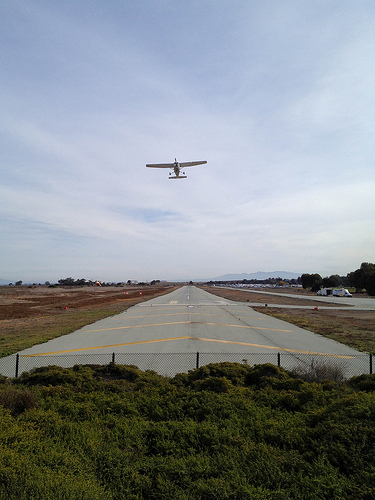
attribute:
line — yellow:
[14, 334, 362, 362]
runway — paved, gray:
[1, 286, 374, 379]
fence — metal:
[2, 352, 374, 374]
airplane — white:
[145, 159, 207, 181]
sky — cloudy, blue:
[1, 0, 374, 284]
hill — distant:
[206, 268, 300, 280]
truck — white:
[334, 287, 355, 299]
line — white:
[140, 301, 241, 308]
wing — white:
[178, 159, 208, 168]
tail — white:
[170, 175, 187, 179]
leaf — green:
[2, 375, 7, 379]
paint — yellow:
[65, 320, 315, 333]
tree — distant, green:
[54, 277, 73, 288]